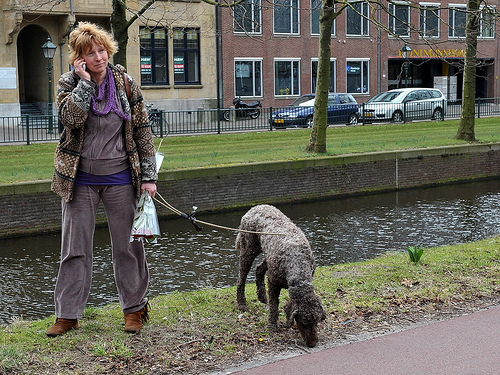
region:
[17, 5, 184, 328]
woman wearing a purple scarf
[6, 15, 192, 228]
woman talking on cell phone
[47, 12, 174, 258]
woman wearing a sweater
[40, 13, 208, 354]
woman wearng a jogging suit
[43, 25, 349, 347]
woman holdind a dog by leash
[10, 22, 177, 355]
woman wearing brown boots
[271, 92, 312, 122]
blue car on a street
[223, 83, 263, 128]
motor cycle next to a wall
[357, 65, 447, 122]
van on a street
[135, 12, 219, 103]
windows on a building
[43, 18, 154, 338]
Lady walking a dog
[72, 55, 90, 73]
Cell phone held by a lady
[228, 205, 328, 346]
Gray poodle on a walk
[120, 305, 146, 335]
Brown suede shoes on a lady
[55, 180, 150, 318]
Gray pants on a lady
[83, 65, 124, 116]
Purple scarf on a lady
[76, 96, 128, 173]
Gray jacket on a lady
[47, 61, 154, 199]
Brown patterned sweater on a lady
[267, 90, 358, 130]
Blue car parked in the background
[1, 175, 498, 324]
Canal behind a lady with a dog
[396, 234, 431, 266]
small green plant on side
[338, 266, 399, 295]
green grass on the surface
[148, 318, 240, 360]
brown bald spot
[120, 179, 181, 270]
green paper in woman's hand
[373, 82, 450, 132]
silver van parked on road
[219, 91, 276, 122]
black bike on side walk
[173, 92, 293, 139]
silver barrier on side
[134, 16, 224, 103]
large window in building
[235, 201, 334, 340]
dog foraging on the ground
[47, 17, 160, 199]
woman talking on the phone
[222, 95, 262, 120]
A black motorcycle near a building.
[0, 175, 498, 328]
A body of water.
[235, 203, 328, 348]
A black poodle on a leash.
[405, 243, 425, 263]
A plant.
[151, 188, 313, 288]
A leash.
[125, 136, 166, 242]
A bouquet of flowers.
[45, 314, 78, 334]
A shoe on the right foot.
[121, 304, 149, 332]
A shoe on the left foot.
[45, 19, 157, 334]
A woman standing near a body of water.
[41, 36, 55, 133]
A lightpost.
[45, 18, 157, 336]
Woman standing by a river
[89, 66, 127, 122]
Scarf on the woman's neck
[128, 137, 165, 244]
Flowers in the woman's left hand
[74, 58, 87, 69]
Cellphone in the woman's left hand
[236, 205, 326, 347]
Dog standing next to the woman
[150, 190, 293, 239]
Rope on the dog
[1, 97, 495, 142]
Metal fence along the road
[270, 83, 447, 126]
Cars on the road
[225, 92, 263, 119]
Motorcycle parked by the building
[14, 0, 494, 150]
Trees along the river